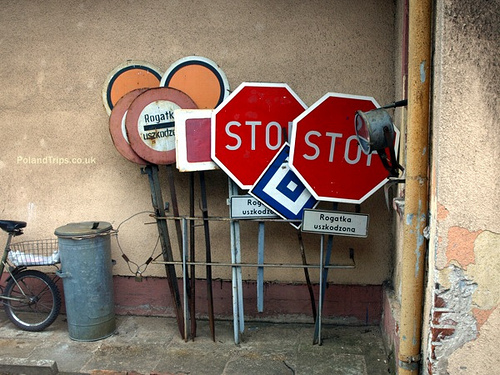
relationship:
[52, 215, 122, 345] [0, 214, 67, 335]
trash can beside bicycle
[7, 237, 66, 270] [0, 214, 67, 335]
basket on bicycle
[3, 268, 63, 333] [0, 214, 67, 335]
wheel on bicycle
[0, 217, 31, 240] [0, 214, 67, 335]
seat of bicycle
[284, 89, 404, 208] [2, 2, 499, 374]
stop sign against building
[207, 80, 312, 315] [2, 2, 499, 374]
stop sign against building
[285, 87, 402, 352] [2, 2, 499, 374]
stop sign against building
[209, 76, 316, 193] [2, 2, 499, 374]
stop sign against building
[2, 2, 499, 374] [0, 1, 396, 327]
building has side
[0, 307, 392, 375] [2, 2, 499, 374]
sidewalk in front of building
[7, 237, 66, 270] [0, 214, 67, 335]
basket attached to bicycle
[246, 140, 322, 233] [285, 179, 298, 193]
sign has central diamond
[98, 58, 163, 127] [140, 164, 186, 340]
sign has post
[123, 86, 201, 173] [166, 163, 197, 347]
sign has post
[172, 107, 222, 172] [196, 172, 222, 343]
sign has post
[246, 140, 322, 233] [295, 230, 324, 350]
sign has post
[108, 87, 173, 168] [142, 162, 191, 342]
sign has post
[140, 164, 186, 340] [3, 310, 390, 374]
post rests on ground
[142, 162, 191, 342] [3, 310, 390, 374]
post rests on ground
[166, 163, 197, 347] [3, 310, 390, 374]
post rests on ground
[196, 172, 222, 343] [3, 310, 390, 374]
post rests on ground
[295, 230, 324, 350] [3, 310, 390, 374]
post rests on ground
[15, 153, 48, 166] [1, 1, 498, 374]
'poland' stamped on photo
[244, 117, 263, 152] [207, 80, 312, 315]
t in stop sign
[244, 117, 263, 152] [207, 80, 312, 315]
t on stop sign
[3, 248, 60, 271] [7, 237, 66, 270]
cloth in basket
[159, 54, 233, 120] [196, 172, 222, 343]
sign has post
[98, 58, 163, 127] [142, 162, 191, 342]
sign has post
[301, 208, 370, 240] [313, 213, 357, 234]
sign has polish designation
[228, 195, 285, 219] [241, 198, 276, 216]
sign has polish designation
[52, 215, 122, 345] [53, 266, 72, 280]
trash can has handle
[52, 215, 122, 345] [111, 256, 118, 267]
trash can has handle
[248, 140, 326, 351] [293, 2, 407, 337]
road sign in corner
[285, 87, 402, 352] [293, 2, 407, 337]
stop sign in corner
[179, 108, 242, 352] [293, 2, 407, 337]
road sign in corner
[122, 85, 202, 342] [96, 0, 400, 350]
road sign in corner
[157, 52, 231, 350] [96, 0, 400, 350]
road sign in corner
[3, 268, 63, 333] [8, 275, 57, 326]
wheel has spokes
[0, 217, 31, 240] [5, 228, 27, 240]
seat has springs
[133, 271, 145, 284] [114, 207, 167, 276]
padlock has chain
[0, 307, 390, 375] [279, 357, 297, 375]
pavement has crack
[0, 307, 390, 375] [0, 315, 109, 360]
pavement has dirt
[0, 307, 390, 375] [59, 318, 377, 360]
pavement has water damage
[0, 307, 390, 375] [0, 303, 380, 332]
pavement needs re-grouting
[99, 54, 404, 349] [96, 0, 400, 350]
signs in corner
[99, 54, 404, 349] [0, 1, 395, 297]
signs against wall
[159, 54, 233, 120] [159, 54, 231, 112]
sign has rim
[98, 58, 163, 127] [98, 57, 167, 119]
sign has rim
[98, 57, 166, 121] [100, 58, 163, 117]
orange sign has border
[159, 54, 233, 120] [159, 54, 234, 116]
orange sign has border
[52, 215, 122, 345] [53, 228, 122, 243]
trash can has bag as liner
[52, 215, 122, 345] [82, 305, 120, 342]
trash can starting to rust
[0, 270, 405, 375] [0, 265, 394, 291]
bricks need re-tarring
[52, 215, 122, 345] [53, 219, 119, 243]
trash can has lid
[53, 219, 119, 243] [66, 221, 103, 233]
lid has strap for lifting